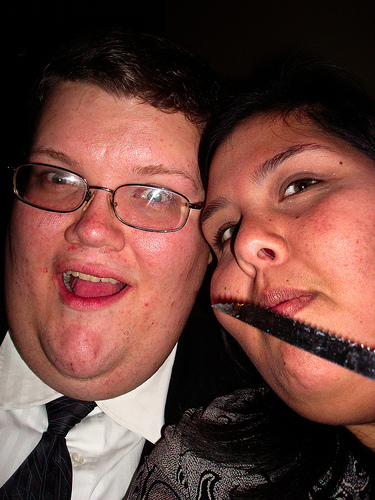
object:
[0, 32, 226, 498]
man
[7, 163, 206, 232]
glasses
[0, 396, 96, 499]
tie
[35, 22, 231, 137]
hair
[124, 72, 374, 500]
woman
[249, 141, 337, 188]
eyebrow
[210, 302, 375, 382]
knife blade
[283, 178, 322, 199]
eyes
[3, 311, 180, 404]
double chin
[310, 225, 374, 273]
freckles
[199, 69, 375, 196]
hair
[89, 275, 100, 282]
teeth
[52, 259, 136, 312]
mouth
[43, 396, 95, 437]
knot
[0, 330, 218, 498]
suit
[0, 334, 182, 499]
shirt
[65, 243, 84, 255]
acne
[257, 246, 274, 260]
nostril